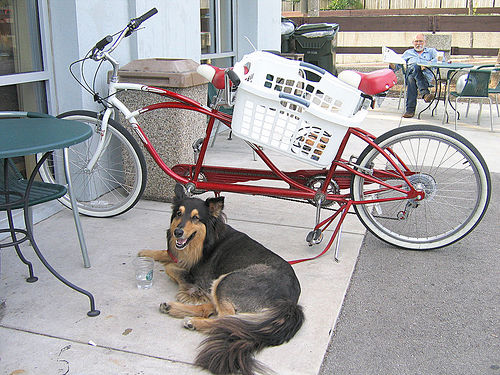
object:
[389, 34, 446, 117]
man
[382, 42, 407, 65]
newspaper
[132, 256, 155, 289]
cup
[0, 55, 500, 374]
ground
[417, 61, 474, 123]
table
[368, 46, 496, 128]
background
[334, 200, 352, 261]
kickstand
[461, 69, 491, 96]
chair back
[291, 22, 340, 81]
can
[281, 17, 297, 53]
can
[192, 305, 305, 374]
dog tail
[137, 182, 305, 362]
collie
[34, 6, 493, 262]
bicycle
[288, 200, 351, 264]
leash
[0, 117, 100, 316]
table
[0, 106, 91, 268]
chair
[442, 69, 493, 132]
chair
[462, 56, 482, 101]
back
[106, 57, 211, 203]
trashcan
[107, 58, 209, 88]
lid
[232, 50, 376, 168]
basket